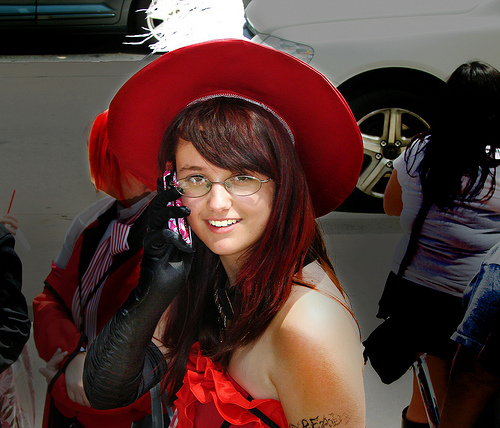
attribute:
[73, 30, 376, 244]
hat — red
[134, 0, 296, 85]
feathers — white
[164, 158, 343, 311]
girl — smiling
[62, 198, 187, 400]
glove — black